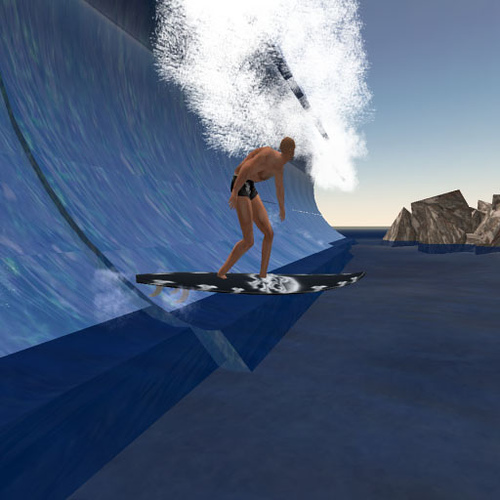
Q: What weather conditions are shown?
A: It is clear.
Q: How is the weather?
A: It is clear.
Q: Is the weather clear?
A: Yes, it is clear.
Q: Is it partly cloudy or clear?
A: It is clear.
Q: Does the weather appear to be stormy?
A: No, it is clear.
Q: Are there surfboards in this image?
A: Yes, there is a surfboard.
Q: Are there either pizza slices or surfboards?
A: Yes, there is a surfboard.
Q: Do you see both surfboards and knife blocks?
A: No, there is a surfboard but no knife blocks.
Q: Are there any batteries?
A: No, there are no batteries.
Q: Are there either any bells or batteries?
A: No, there are no batteries or bells.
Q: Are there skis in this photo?
A: No, there are no skis.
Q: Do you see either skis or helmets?
A: No, there are no skis or helmets.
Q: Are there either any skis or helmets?
A: No, there are no skis or helmets.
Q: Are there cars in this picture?
A: No, there are no cars.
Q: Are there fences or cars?
A: No, there are no cars or fences.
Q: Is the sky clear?
A: Yes, the sky is clear.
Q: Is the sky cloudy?
A: No, the sky is clear.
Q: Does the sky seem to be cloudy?
A: No, the sky is clear.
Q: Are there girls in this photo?
A: No, there are no girls.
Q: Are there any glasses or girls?
A: No, there are no girls or glasses.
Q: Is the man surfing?
A: Yes, the man is surfing.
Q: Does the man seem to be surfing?
A: Yes, the man is surfing.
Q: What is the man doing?
A: The man is surfing.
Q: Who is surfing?
A: The man is surfing.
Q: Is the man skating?
A: No, the man is surfing.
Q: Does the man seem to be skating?
A: No, the man is surfing.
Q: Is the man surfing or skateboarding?
A: The man is surfing.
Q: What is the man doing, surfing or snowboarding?
A: The man is surfing.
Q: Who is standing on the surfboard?
A: The man is standing on the surfboard.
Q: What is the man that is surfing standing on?
A: The man is standing on the surfboard.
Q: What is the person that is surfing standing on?
A: The man is standing on the surfboard.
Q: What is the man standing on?
A: The man is standing on the surfboard.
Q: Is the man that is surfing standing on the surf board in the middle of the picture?
A: Yes, the man is standing on the surfboard.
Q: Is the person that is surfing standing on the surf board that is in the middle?
A: Yes, the man is standing on the surfboard.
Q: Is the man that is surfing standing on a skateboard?
A: No, the man is standing on the surfboard.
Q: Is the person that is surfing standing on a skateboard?
A: No, the man is standing on the surfboard.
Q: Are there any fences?
A: No, there are no fences.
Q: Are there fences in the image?
A: No, there are no fences.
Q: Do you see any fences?
A: No, there are no fences.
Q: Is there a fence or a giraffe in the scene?
A: No, there are no fences or giraffes.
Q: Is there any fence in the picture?
A: No, there are no fences.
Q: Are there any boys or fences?
A: No, there are no fences or boys.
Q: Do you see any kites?
A: No, there are no kites.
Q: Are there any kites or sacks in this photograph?
A: No, there are no kites or sacks.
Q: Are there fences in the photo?
A: No, there are no fences.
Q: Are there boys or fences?
A: No, there are no fences or boys.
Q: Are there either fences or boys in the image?
A: No, there are no fences or boys.